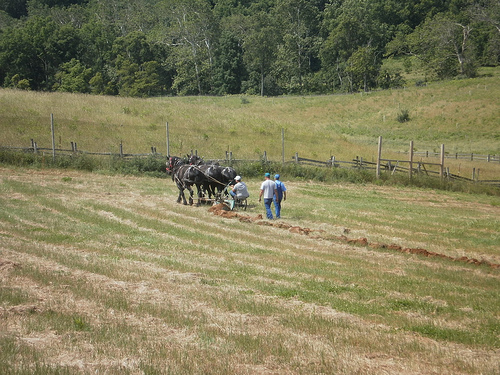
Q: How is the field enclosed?
A: Fence.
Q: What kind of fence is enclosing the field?
A: Wood fence.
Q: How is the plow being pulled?
A: Horses.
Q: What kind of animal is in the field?
A: Horse.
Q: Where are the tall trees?
A: Background bordering gree field beyond the wooden fence.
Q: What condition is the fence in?
A: Disrepair.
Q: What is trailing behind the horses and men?
A: Brown dirt trail.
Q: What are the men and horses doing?
A: Plowing the field.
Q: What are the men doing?
A: Farming.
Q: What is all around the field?
A: A fence.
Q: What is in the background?
A: Trees.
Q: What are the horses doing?
A: Pulling a plow.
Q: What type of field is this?
A: Grass.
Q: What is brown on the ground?
A: Dried grass.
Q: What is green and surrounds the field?
A: Trees.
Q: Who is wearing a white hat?
A: The man behind the horses.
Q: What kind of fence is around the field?
A: A wood fence.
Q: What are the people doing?
A: Walking.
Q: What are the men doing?
A: Workign.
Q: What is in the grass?
A: Cows.